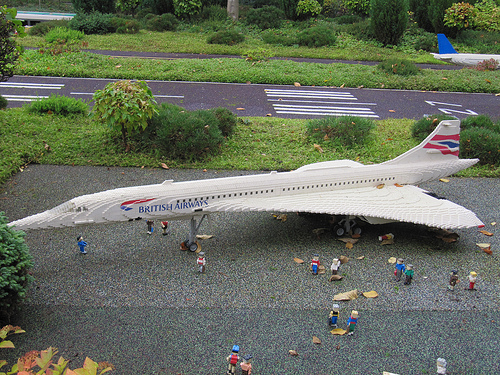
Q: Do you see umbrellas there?
A: No, there are no umbrellas.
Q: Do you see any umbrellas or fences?
A: No, there are no umbrellas or fences.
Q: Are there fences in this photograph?
A: No, there are no fences.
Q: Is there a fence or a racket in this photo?
A: No, there are no fences or rackets.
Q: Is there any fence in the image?
A: No, there are no fences.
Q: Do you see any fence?
A: No, there are no fences.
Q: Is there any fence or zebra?
A: No, there are no fences or zebras.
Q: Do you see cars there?
A: No, there are no cars.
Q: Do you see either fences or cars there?
A: No, there are no cars or fences.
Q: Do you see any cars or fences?
A: No, there are no cars or fences.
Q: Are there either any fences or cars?
A: No, there are no cars or fences.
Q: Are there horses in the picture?
A: No, there are no horses.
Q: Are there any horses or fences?
A: No, there are no horses or fences.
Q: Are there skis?
A: No, there are no skis.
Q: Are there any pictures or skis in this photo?
A: No, there are no skis or pictures.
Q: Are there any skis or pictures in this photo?
A: No, there are no skis or pictures.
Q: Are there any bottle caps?
A: No, there are no bottle caps.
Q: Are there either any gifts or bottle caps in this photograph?
A: No, there are no bottle caps or gifts.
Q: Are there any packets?
A: No, there are no packets.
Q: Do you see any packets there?
A: No, there are no packets.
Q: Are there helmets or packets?
A: No, there are no packets or helmets.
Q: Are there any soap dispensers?
A: No, there are no soap dispensers.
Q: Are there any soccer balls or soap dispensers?
A: No, there are no soap dispensers or soccer balls.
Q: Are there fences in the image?
A: No, there are no fences.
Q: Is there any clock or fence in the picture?
A: No, there are no fences or clocks.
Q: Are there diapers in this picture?
A: No, there are no diapers.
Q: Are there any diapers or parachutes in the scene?
A: No, there are no diapers or parachutes.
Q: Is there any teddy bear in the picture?
A: No, there are no teddy bears.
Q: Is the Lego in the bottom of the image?
A: Yes, the Lego is in the bottom of the image.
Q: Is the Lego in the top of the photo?
A: No, the Lego is in the bottom of the image.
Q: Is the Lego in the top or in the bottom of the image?
A: The Lego is in the bottom of the image.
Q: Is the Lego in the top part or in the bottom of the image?
A: The Lego is in the bottom of the image.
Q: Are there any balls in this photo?
A: No, there are no balls.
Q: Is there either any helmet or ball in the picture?
A: No, there are no balls or helmets.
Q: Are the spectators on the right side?
A: Yes, the spectators are on the right of the image.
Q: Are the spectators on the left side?
A: No, the spectators are on the right of the image.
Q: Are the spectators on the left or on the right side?
A: The spectators are on the right of the image.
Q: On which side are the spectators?
A: The spectators are on the right of the image.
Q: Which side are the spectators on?
A: The spectators are on the right of the image.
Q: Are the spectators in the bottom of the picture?
A: Yes, the spectators are in the bottom of the image.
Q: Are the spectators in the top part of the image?
A: No, the spectators are in the bottom of the image.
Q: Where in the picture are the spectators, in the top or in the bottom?
A: The spectators are in the bottom of the image.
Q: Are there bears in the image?
A: No, there are no bears.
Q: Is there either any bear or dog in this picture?
A: No, there are no bears or dogs.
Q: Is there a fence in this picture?
A: No, there are no fences.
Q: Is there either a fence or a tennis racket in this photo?
A: No, there are no fences or rackets.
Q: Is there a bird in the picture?
A: No, there are no birds.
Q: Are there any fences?
A: No, there are no fences.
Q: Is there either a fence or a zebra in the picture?
A: No, there are no fences or zebras.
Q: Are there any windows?
A: Yes, there are windows.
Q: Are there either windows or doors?
A: Yes, there are windows.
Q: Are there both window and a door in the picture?
A: No, there are windows but no doors.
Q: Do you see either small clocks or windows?
A: Yes, there are small windows.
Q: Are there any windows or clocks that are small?
A: Yes, the windows are small.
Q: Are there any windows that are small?
A: Yes, there are small windows.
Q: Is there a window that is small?
A: Yes, there are windows that are small.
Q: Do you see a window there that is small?
A: Yes, there are windows that are small.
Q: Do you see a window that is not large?
A: Yes, there are small windows.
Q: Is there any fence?
A: No, there are no fences.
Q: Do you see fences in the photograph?
A: No, there are no fences.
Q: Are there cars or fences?
A: No, there are no fences or cars.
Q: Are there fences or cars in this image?
A: No, there are no fences or cars.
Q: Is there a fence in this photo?
A: No, there are no fences.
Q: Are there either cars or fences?
A: No, there are no fences or cars.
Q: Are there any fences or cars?
A: No, there are no fences or cars.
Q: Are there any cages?
A: No, there are no cages.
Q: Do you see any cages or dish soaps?
A: No, there are no cages or dish soaps.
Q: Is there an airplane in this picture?
A: Yes, there is an airplane.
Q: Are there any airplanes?
A: Yes, there is an airplane.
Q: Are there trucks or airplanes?
A: Yes, there is an airplane.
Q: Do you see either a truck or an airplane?
A: Yes, there is an airplane.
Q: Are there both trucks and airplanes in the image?
A: No, there is an airplane but no trucks.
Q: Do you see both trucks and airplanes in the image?
A: No, there is an airplane but no trucks.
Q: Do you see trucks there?
A: No, there are no trucks.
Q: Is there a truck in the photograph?
A: No, there are no trucks.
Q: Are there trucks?
A: No, there are no trucks.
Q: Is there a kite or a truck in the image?
A: No, there are no trucks or kites.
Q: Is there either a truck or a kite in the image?
A: No, there are no trucks or kites.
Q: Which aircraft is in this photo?
A: The aircraft is an airplane.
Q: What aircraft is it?
A: The aircraft is an airplane.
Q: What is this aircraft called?
A: This is an airplane.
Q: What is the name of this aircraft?
A: This is an airplane.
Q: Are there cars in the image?
A: No, there are no cars.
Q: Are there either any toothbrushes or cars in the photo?
A: No, there are no cars or toothbrushes.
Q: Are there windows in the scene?
A: Yes, there are windows.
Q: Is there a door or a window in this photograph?
A: Yes, there are windows.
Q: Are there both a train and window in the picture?
A: No, there are windows but no trains.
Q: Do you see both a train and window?
A: No, there are windows but no trains.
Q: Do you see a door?
A: No, there are no doors.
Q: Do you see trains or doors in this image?
A: No, there are no doors or trains.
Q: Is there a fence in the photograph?
A: No, there are no fences.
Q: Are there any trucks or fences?
A: No, there are no fences or trucks.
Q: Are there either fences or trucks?
A: No, there are no fences or trucks.